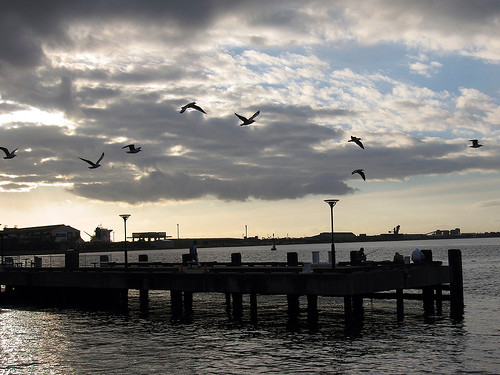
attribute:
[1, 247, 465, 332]
dock — wood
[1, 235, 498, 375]
water — calm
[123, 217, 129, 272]
post — black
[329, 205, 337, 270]
right post — black `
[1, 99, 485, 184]
birds — flying, gray, small, black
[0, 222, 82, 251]
building — large, far away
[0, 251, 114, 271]
railing — metal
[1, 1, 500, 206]
clouds — white, gray, large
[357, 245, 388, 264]
man — fishing, fishign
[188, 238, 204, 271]
pedestrian — walking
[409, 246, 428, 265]
person — fishing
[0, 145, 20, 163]
bird — flying, gray, small, black, large, flyhing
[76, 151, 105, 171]
bird 2 — flying, gray, small, black, large, flyign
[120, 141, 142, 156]
bird 3 — flyign, gray, small, black, large, flying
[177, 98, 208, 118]
bird — flying, small, black, large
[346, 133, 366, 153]
bird — flying, gray, small, black, large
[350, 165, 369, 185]
bird — flying, small, black, large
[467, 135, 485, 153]
bird — flying, gray, small, black, large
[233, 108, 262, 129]
bird — small, black, large